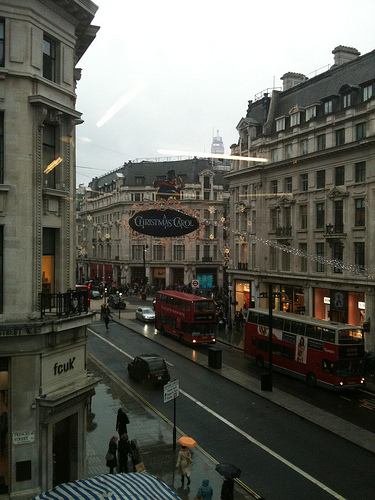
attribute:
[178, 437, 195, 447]
umbrella — orange, yellow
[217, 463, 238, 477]
umbrella — black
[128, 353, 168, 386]
car — black, on road, in street, small, dark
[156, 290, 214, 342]
bus — red, double level, double-decker, on street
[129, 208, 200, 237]
sign — black, large, above street, festive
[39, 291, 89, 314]
railing — black, metal, on balcony, above sign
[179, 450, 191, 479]
coat — white, a duster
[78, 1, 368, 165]
sky — gray, bright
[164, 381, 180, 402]
sign — white, on street, on side of road, on pole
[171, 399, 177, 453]
post — black, tall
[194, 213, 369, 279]
strands — few, lights, christmas lights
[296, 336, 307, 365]
advertisement — on bus, advertising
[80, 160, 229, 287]
building — in background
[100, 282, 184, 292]
people — in front of store, in a group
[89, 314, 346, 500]
line — white, in street, going down street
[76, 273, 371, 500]
street — in city, commerical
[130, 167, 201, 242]
decorations — over street, elevated, for holiday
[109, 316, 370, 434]
island — thin, long, in middle of road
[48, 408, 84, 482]
doorway — in building, at an angle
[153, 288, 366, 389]
buses — double-decker, on side of road, two-story, on street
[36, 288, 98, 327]
terrace — above sign, small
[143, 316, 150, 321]
headlights — bright, on car, on vehicle, on front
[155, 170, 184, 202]
image — on top of building, a man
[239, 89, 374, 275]
windows — on building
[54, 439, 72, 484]
door — on building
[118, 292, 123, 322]
light — on sidewalk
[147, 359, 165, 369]
window — on car, in rear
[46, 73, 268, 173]
lights — reflected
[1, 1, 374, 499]
glass — reflecting lights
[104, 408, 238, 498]
people — on sidewalk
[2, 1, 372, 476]
buildings — large, on sides of street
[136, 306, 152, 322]
vehicle — behind bus, small, grey